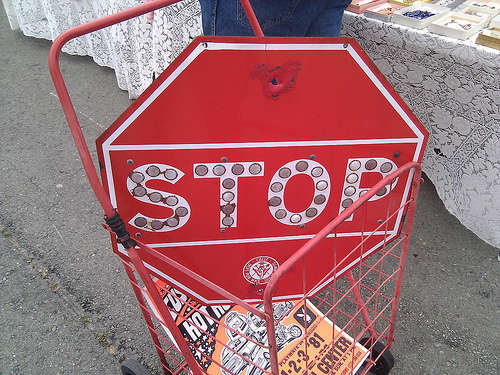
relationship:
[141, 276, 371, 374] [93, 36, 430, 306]
poster under sign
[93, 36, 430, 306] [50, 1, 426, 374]
sign inside cart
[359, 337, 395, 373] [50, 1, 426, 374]
wheel attached to cart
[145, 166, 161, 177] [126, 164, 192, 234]
spot located on letter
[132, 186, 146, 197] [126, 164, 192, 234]
spot located on letter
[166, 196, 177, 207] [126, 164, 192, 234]
spot located on letter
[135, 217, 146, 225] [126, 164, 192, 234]
spot located on letter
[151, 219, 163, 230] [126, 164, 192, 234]
spot located on letter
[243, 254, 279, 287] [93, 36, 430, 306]
logo printed on sign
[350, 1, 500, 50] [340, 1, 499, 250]
jewelry on top of table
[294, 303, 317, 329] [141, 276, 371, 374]
playboy bunny printed on poster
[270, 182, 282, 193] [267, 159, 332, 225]
spot located on letter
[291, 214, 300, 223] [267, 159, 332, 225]
spot located on letter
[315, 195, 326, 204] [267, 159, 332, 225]
spot located on letter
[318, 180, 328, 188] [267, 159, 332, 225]
spot located on letter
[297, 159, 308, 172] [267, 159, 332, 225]
spot located on letter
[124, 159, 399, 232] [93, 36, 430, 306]
stop printed on sign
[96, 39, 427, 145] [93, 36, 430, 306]
top of sign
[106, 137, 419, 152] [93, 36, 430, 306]
line printed on sign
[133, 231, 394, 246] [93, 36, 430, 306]
line printed on sign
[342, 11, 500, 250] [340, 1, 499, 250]
tablecloth on top of table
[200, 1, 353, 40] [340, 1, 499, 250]
person next to table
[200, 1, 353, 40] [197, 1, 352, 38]
person wearing jeans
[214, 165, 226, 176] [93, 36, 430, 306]
spot on surface of sign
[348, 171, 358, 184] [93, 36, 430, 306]
spot on surface of sign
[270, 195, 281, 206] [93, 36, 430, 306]
spot on surface of sign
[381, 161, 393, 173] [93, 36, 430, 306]
spot on surface of sign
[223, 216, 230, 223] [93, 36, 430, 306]
spot on surface of sign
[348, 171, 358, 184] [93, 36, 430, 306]
spot locate on sign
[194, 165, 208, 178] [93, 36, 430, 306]
spot located on sign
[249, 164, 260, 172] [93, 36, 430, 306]
spot located on sign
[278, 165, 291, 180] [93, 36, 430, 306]
spot located on sign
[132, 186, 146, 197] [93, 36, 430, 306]
spot located on sign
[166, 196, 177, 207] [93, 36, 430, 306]
spot located on sign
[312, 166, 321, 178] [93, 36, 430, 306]
spot located on sign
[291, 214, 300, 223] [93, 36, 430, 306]
spot located on sign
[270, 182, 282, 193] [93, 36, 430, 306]
spot located on sign